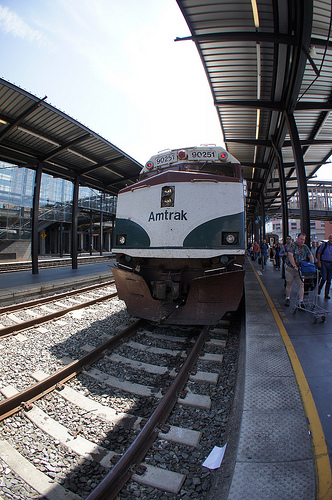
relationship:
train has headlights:
[104, 139, 253, 332] [111, 231, 240, 247]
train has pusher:
[104, 139, 253, 332] [115, 264, 242, 328]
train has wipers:
[104, 139, 253, 332] [146, 159, 210, 173]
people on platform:
[245, 223, 330, 312] [211, 332, 279, 497]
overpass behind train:
[43, 180, 331, 220] [101, 137, 260, 339]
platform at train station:
[211, 332, 279, 497] [4, 7, 326, 498]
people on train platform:
[245, 223, 330, 312] [209, 74, 330, 496]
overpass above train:
[43, 180, 331, 220] [80, 100, 258, 324]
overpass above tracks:
[43, 180, 331, 220] [7, 272, 242, 494]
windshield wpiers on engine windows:
[161, 160, 211, 169] [131, 152, 247, 193]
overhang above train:
[179, 2, 329, 231] [104, 139, 253, 332]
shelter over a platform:
[0, 74, 115, 193] [0, 261, 104, 302]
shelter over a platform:
[171, 0, 322, 141] [211, 332, 279, 497]